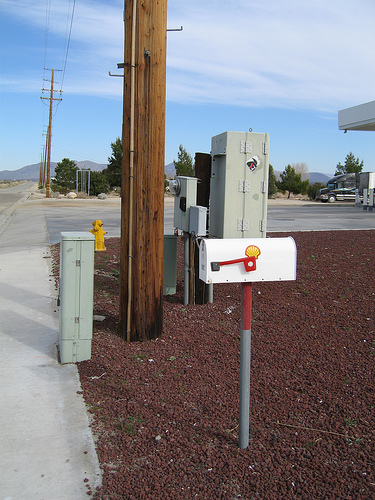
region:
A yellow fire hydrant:
[88, 216, 112, 251]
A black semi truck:
[315, 168, 359, 209]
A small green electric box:
[52, 226, 101, 362]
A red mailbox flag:
[210, 255, 255, 274]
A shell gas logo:
[240, 240, 257, 255]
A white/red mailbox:
[195, 227, 313, 452]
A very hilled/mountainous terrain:
[2, 157, 114, 184]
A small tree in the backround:
[276, 163, 306, 202]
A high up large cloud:
[92, 0, 374, 100]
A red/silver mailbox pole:
[235, 283, 258, 450]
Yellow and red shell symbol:
[245, 243, 263, 258]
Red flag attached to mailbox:
[212, 255, 255, 272]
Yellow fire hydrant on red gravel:
[90, 217, 106, 248]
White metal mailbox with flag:
[196, 234, 292, 276]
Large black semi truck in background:
[316, 169, 370, 199]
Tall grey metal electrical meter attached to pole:
[168, 173, 193, 303]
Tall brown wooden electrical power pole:
[38, 62, 59, 192]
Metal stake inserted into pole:
[105, 68, 120, 74]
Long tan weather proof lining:
[124, 0, 130, 336]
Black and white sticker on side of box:
[245, 152, 260, 170]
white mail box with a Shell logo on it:
[193, 232, 307, 455]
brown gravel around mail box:
[149, 325, 356, 489]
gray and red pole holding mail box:
[227, 278, 260, 451]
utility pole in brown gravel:
[118, 0, 167, 344]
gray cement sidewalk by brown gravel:
[0, 365, 101, 493]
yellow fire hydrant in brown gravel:
[79, 217, 115, 259]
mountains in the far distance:
[4, 151, 110, 190]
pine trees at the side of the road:
[42, 148, 116, 196]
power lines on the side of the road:
[34, 0, 81, 106]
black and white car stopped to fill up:
[316, 185, 362, 206]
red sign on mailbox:
[214, 254, 267, 281]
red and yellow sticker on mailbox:
[237, 239, 272, 265]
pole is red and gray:
[234, 279, 263, 461]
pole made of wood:
[115, 0, 183, 353]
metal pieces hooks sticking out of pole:
[93, 5, 188, 93]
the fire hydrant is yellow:
[80, 206, 123, 266]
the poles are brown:
[35, 51, 80, 216]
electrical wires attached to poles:
[33, 1, 90, 157]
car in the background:
[319, 172, 363, 214]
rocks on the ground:
[70, 236, 373, 498]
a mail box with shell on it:
[195, 235, 298, 284]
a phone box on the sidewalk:
[50, 229, 104, 366]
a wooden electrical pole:
[109, 5, 173, 343]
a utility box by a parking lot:
[205, 127, 268, 237]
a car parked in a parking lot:
[317, 186, 360, 202]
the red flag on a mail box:
[210, 252, 258, 273]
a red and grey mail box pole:
[231, 274, 264, 450]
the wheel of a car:
[325, 191, 337, 203]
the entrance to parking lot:
[4, 196, 57, 249]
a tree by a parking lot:
[276, 165, 304, 201]